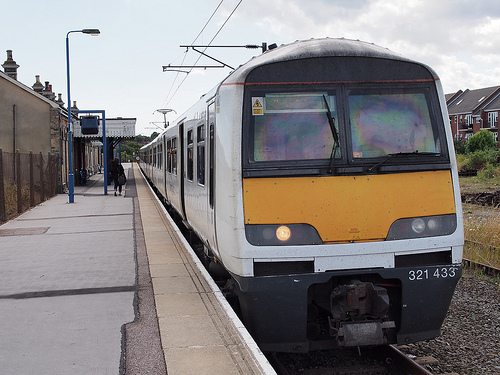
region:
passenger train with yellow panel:
[137, 36, 465, 355]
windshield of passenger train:
[247, 80, 452, 171]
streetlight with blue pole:
[61, 20, 102, 212]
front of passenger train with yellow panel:
[216, 32, 466, 351]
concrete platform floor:
[23, 213, 148, 374]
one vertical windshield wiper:
[318, 90, 347, 160]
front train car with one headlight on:
[223, 36, 467, 350]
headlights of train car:
[244, 214, 459, 249]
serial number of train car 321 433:
[405, 263, 460, 284]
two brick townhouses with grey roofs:
[451, 82, 498, 144]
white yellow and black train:
[137, 70, 437, 330]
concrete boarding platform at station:
[30, 141, 176, 342]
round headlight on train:
[268, 223, 301, 244]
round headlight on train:
[409, 205, 426, 253]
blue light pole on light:
[56, 34, 95, 216]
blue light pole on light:
[89, 109, 123, 197]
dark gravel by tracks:
[418, 324, 498, 374]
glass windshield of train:
[243, 79, 451, 163]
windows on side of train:
[134, 125, 220, 171]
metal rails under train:
[375, 336, 409, 373]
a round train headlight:
[277, 221, 292, 241]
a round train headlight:
[409, 215, 426, 233]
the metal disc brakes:
[330, 286, 393, 345]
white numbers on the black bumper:
[409, 265, 459, 282]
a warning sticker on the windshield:
[249, 95, 268, 119]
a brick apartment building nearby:
[456, 86, 498, 140]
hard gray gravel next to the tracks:
[444, 285, 496, 373]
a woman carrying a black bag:
[106, 154, 126, 194]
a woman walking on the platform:
[107, 159, 132, 192]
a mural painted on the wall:
[0, 90, 67, 212]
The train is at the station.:
[120, 29, 460, 356]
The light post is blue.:
[53, 10, 113, 215]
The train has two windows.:
[232, 68, 457, 175]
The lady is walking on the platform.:
[102, 142, 149, 213]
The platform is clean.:
[20, 193, 193, 352]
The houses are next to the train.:
[412, 60, 499, 171]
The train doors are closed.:
[155, 115, 225, 235]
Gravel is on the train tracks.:
[411, 258, 498, 372]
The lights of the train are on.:
[257, 222, 329, 252]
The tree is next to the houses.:
[452, 90, 498, 187]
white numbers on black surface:
[402, 263, 463, 283]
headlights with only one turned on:
[255, 222, 318, 244]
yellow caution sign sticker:
[249, 93, 266, 119]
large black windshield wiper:
[314, 90, 348, 173]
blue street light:
[62, 25, 103, 210]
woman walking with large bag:
[107, 148, 134, 195]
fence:
[6, 146, 63, 211]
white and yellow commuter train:
[132, 41, 472, 359]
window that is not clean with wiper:
[342, 80, 443, 170]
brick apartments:
[457, 81, 499, 142]